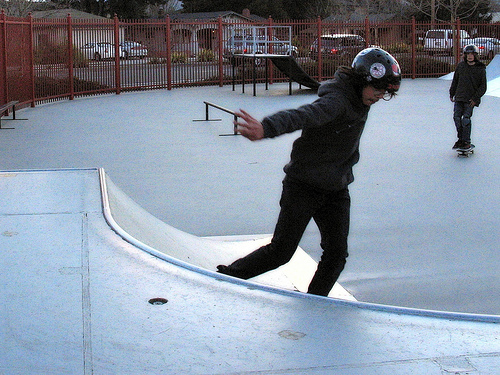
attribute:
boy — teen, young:
[448, 42, 483, 143]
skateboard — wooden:
[452, 137, 478, 157]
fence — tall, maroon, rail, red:
[4, 10, 499, 121]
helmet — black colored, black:
[350, 41, 401, 92]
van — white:
[423, 30, 472, 54]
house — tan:
[6, 3, 135, 59]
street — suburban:
[18, 54, 499, 84]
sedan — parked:
[82, 34, 124, 64]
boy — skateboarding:
[211, 39, 401, 320]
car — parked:
[114, 36, 152, 59]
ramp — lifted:
[3, 169, 498, 374]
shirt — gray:
[259, 66, 371, 193]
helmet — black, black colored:
[465, 45, 480, 55]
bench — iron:
[0, 94, 24, 142]